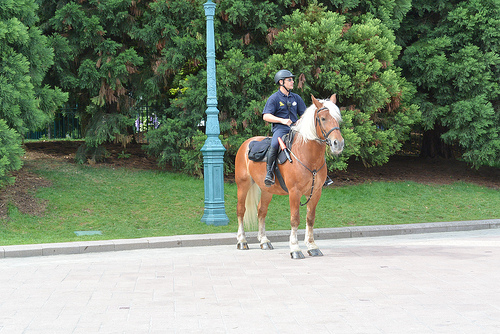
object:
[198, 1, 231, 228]
pole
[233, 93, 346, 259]
horse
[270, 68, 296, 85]
helmet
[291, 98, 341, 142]
mane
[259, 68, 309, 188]
officer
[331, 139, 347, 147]
nose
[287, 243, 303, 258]
front foot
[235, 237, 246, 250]
back foot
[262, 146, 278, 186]
boot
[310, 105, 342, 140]
harness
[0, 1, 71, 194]
pinetree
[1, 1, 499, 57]
park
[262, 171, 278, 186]
foot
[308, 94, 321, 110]
ear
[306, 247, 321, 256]
hoof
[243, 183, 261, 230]
tail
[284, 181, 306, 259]
leg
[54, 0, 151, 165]
tree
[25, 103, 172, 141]
fence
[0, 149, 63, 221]
dirt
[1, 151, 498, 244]
grass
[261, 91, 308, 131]
suit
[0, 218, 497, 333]
street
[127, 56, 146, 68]
leaves